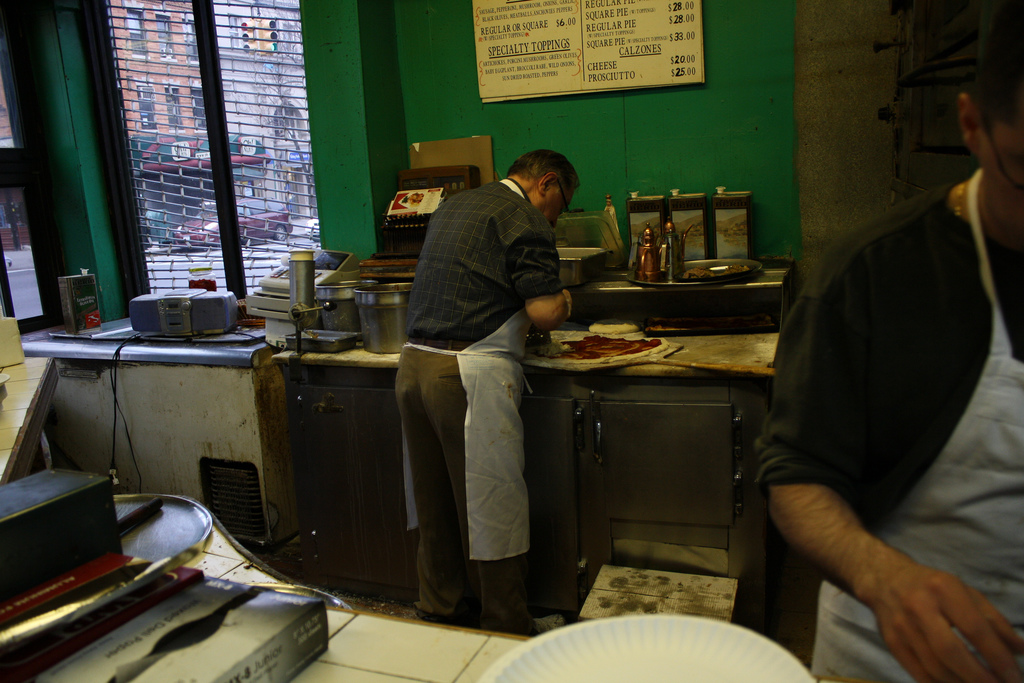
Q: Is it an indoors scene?
A: Yes, it is indoors.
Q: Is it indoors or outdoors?
A: It is indoors.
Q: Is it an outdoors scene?
A: No, it is indoors.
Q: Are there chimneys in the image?
A: No, there are no chimneys.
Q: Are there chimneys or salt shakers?
A: No, there are no chimneys or salt shakers.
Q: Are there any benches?
A: No, there are no benches.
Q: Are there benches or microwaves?
A: No, there are no benches or microwaves.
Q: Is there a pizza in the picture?
A: Yes, there is a pizza.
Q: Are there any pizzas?
A: Yes, there is a pizza.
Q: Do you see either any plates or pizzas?
A: Yes, there is a pizza.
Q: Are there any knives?
A: No, there are no knives.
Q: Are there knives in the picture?
A: No, there are no knives.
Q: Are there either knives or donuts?
A: No, there are no knives or donuts.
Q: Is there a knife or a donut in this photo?
A: No, there are no knives or donuts.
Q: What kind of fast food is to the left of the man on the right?
A: The food is a pizza.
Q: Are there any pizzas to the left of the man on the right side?
A: Yes, there is a pizza to the left of the man.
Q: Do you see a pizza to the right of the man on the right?
A: No, the pizza is to the left of the man.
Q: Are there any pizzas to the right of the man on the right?
A: No, the pizza is to the left of the man.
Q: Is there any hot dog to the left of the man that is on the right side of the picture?
A: No, there is a pizza to the left of the man.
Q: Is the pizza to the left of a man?
A: Yes, the pizza is to the left of a man.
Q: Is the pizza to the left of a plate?
A: No, the pizza is to the left of a man.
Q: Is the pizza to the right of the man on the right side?
A: No, the pizza is to the left of the man.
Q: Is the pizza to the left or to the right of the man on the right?
A: The pizza is to the left of the man.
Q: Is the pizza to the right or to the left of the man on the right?
A: The pizza is to the left of the man.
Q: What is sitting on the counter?
A: The pizza is sitting on the counter.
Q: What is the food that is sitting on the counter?
A: The food is a pizza.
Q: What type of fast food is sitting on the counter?
A: The food is a pizza.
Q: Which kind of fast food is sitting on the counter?
A: The food is a pizza.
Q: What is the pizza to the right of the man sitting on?
A: The pizza is sitting on the counter.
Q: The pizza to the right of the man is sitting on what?
A: The pizza is sitting on the counter.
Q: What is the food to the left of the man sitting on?
A: The pizza is sitting on the counter.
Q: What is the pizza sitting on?
A: The pizza is sitting on the counter.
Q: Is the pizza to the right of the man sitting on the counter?
A: Yes, the pizza is sitting on the counter.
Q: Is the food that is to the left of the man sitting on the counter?
A: Yes, the pizza is sitting on the counter.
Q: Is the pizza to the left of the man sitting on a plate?
A: No, the pizza is sitting on the counter.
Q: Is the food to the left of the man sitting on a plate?
A: No, the pizza is sitting on the counter.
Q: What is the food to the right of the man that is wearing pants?
A: The food is a pizza.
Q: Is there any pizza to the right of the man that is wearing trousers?
A: Yes, there is a pizza to the right of the man.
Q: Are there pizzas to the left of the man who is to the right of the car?
A: No, the pizza is to the right of the man.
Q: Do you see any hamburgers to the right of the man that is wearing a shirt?
A: No, there is a pizza to the right of the man.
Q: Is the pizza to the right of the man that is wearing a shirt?
A: Yes, the pizza is to the right of the man.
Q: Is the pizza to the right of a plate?
A: No, the pizza is to the right of the man.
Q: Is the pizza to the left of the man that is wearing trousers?
A: No, the pizza is to the right of the man.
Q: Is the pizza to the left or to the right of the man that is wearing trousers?
A: The pizza is to the right of the man.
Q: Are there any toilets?
A: No, there are no toilets.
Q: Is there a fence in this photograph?
A: No, there are no fences.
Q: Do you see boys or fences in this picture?
A: No, there are no fences or boys.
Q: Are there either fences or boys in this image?
A: No, there are no fences or boys.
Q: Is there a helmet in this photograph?
A: No, there are no helmets.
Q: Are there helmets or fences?
A: No, there are no helmets or fences.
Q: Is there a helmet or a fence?
A: No, there are no helmets or fences.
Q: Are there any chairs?
A: No, there are no chairs.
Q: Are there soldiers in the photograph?
A: No, there are no soldiers.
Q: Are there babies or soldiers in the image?
A: No, there are no soldiers or babies.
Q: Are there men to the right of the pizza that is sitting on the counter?
A: Yes, there is a man to the right of the pizza.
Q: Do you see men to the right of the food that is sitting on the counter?
A: Yes, there is a man to the right of the pizza.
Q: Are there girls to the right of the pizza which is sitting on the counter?
A: No, there is a man to the right of the pizza.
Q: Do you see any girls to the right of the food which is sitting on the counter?
A: No, there is a man to the right of the pizza.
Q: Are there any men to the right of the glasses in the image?
A: Yes, there is a man to the right of the glasses.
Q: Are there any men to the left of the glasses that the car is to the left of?
A: No, the man is to the right of the glasses.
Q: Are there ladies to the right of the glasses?
A: No, there is a man to the right of the glasses.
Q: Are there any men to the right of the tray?
A: Yes, there is a man to the right of the tray.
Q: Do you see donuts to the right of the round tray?
A: No, there is a man to the right of the tray.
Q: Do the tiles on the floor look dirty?
A: Yes, the tiles are dirty.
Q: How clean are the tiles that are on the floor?
A: The tiles are dirty.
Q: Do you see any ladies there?
A: No, there are no ladies.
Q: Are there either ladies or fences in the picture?
A: No, there are no ladies or fences.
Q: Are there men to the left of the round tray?
A: Yes, there is a man to the left of the tray.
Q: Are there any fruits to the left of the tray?
A: No, there is a man to the left of the tray.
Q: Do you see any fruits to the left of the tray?
A: No, there is a man to the left of the tray.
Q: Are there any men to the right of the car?
A: Yes, there is a man to the right of the car.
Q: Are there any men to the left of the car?
A: No, the man is to the right of the car.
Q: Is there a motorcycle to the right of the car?
A: No, there is a man to the right of the car.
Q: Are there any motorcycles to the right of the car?
A: No, there is a man to the right of the car.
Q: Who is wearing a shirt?
A: The man is wearing a shirt.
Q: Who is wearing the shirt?
A: The man is wearing a shirt.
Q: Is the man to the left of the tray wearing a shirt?
A: Yes, the man is wearing a shirt.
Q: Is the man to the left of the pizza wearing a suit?
A: No, the man is wearing a shirt.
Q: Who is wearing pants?
A: The man is wearing pants.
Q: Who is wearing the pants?
A: The man is wearing pants.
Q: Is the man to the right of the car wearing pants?
A: Yes, the man is wearing pants.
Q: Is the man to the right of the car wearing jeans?
A: No, the man is wearing pants.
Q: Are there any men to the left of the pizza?
A: Yes, there is a man to the left of the pizza.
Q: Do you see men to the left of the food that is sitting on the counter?
A: Yes, there is a man to the left of the pizza.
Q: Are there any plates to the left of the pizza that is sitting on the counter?
A: No, there is a man to the left of the pizza.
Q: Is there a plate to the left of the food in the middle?
A: No, there is a man to the left of the pizza.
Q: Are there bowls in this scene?
A: No, there are no bowls.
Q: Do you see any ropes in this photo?
A: No, there are no ropes.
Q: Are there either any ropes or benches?
A: No, there are no ropes or benches.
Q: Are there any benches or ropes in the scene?
A: No, there are no ropes or benches.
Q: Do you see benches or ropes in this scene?
A: No, there are no ropes or benches.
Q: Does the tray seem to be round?
A: Yes, the tray is round.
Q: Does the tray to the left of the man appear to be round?
A: Yes, the tray is round.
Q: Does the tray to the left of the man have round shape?
A: Yes, the tray is round.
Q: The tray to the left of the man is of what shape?
A: The tray is round.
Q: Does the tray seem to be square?
A: No, the tray is round.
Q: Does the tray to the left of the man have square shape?
A: No, the tray is round.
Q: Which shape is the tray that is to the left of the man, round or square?
A: The tray is round.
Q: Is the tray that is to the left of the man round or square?
A: The tray is round.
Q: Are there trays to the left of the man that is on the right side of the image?
A: Yes, there is a tray to the left of the man.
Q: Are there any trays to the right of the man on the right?
A: No, the tray is to the left of the man.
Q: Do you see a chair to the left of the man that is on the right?
A: No, there is a tray to the left of the man.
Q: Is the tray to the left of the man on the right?
A: Yes, the tray is to the left of the man.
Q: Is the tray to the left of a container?
A: No, the tray is to the left of the man.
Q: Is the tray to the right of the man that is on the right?
A: No, the tray is to the left of the man.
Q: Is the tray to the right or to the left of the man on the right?
A: The tray is to the left of the man.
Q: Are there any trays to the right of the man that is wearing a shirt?
A: Yes, there is a tray to the right of the man.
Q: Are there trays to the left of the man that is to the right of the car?
A: No, the tray is to the right of the man.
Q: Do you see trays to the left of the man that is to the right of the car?
A: No, the tray is to the right of the man.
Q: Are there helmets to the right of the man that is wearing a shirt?
A: No, there is a tray to the right of the man.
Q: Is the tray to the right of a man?
A: Yes, the tray is to the right of a man.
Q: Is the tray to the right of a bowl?
A: No, the tray is to the right of a man.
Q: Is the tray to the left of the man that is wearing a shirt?
A: No, the tray is to the right of the man.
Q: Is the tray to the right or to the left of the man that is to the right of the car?
A: The tray is to the right of the man.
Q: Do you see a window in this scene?
A: Yes, there is a window.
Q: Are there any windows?
A: Yes, there is a window.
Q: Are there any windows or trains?
A: Yes, there is a window.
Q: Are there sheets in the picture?
A: No, there are no sheets.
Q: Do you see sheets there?
A: No, there are no sheets.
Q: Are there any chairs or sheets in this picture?
A: No, there are no sheets or chairs.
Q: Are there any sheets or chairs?
A: No, there are no sheets or chairs.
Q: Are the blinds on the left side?
A: Yes, the blinds are on the left of the image.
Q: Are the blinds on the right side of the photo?
A: No, the blinds are on the left of the image.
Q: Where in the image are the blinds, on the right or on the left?
A: The blinds are on the left of the image.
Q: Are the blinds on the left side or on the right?
A: The blinds are on the left of the image.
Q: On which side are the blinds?
A: The blinds are on the left of the image.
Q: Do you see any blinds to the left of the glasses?
A: Yes, there are blinds to the left of the glasses.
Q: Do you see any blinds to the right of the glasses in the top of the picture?
A: No, the blinds are to the left of the glasses.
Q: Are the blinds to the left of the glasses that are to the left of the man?
A: Yes, the blinds are to the left of the glasses.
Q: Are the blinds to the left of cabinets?
A: No, the blinds are to the left of the glasses.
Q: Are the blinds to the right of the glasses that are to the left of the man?
A: No, the blinds are to the left of the glasses.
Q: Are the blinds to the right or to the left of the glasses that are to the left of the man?
A: The blinds are to the left of the glasses.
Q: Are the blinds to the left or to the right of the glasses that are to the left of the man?
A: The blinds are to the left of the glasses.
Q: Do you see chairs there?
A: No, there are no chairs.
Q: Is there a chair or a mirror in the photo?
A: No, there are no chairs or mirrors.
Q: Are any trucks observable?
A: No, there are no trucks.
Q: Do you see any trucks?
A: No, there are no trucks.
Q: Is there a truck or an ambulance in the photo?
A: No, there are no trucks or ambulances.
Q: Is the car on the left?
A: Yes, the car is on the left of the image.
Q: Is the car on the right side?
A: No, the car is on the left of the image.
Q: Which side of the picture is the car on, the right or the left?
A: The car is on the left of the image.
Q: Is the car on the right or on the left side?
A: The car is on the left of the image.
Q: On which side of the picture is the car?
A: The car is on the left of the image.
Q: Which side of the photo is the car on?
A: The car is on the left of the image.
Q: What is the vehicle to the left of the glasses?
A: The vehicle is a car.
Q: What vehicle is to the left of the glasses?
A: The vehicle is a car.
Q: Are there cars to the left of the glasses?
A: Yes, there is a car to the left of the glasses.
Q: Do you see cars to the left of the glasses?
A: Yes, there is a car to the left of the glasses.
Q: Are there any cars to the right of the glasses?
A: No, the car is to the left of the glasses.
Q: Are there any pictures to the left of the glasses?
A: No, there is a car to the left of the glasses.